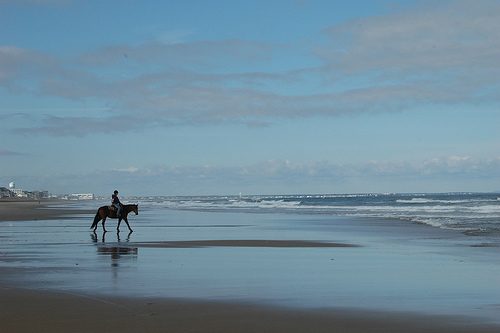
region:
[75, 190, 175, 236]
A man sitting in the horse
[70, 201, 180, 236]
A horse walking near the sea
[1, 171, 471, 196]
Lot of buildings near the sea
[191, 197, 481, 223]
Big size waves in the sea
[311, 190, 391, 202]
A blue color sea water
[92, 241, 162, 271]
Shadow of the man and horse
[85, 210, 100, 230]
Tail of the horse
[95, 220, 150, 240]
Legs of the horse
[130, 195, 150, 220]
Head of the horse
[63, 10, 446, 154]
A blue color sky with clouds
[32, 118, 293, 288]
The horse and rider are on the beach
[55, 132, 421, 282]
Someone going for a ride at the beach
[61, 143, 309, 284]
Someone riding a horse by the sea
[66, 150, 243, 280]
A horse is walking along the coast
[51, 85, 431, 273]
Someone is taking a ride on a nice day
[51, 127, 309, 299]
Someone is enjoying their day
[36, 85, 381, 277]
Someone riding as the tide goes out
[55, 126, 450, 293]
Someone enjoying a beach resort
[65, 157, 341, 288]
A horse walking slowly in the sand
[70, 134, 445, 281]
Horse and rider walking peacefully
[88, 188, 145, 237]
A person riding a horse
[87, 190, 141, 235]
A person on a horse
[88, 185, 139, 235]
A person riding a horse on the beach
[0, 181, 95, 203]
Buildings in the background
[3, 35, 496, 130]
A dark and cloudy sky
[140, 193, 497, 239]
Coastline of the beach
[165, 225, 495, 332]
Shore of the beach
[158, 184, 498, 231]
Choppy water in the ocean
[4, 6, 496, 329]
A dark and cloudy beach scene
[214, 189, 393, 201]
A bridge off in the distance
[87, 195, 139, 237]
horse walking on the beach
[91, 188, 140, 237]
person riding on horse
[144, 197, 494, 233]
waves crashing on beach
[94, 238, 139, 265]
reflection in the sand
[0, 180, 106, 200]
buildings in the background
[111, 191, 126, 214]
person riding on horse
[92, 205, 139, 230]
horse with rider at beach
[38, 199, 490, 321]
wet sand at the beach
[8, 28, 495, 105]
grey clouds in the sky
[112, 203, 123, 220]
blue jeans of person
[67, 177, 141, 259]
a person riding a horse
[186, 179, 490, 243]
the ocean with white waves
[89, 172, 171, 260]
a person riding on a horse on the beach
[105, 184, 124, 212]
a person wearing a black shirt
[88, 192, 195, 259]
a horse walking on a beach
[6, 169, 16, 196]
a large water tank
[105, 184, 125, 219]
a person wearing blue jeans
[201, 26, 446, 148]
white clouds in a blue sky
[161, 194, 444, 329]
a sandy beach by the ocean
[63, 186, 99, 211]
a white building by the ocean